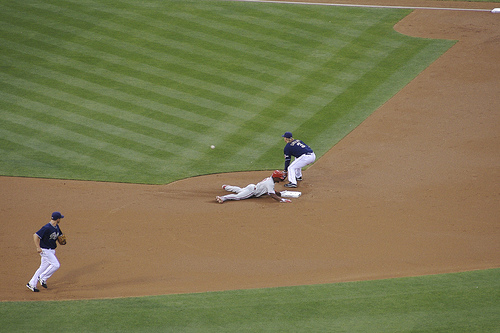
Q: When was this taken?
A: During the day.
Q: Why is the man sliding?
A: To get to base.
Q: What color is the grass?
A: Green.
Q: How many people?
A: Three.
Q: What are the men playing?
A: Baseball.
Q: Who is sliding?
A: Man in red helmet.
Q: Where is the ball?
A: On ground.